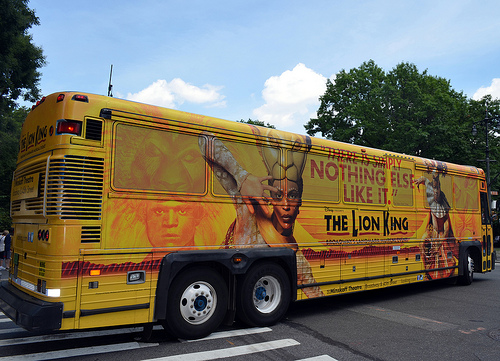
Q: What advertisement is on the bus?
A: Lion King.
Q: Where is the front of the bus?
A: On the right.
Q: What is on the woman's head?
A: Lion hat.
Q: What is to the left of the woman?
A: A man's head.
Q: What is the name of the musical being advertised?
A: The Lion King.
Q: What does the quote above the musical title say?
A: "There is simply nothing else like it.".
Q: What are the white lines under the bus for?
A: Cross walk.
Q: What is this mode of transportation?
A: Bus.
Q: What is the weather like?
A: Clear skies.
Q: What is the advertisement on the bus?
A: Lion King musical.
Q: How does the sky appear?
A: Cloudy.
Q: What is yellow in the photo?
A: Bus.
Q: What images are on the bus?
A: Actors.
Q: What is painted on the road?
A: White stripes.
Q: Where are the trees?
A: Behind bus.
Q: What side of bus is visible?
A: Right side.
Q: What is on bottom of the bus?
A: Tires.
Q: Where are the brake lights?
A: Back of bus.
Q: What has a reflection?
A: Side mirror.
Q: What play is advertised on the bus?
A: The Lion King.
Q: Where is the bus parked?
A: In a parking lot.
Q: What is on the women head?
A: A lion hat.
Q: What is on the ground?
A: White lines.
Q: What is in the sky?
A: Clouds.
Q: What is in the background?
A: Trees.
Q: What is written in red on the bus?
A: There is simply Nothing Else Like It.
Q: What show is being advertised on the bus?
A: The Lion King.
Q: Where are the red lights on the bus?
A: On the top.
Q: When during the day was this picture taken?
A: Afternoon.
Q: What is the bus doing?
A: Sitting in a parking lot.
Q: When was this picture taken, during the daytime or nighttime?
A: Daytime.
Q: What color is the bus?
A: Yellow.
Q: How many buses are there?
A: One.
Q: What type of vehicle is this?
A: Bus.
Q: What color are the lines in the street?
A: White.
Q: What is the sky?
A: Clouds.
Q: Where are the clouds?
A: The sky.